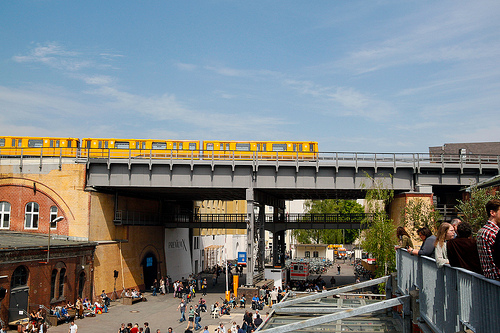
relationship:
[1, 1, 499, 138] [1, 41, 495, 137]
sky has clouds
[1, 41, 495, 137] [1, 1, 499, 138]
clouds in sky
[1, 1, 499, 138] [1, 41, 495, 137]
sky has white clouds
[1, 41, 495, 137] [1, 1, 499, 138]
clouds in blue sky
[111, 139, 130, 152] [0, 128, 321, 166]
window on train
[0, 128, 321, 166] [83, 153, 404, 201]
train on bridge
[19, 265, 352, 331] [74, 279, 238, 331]
people walking on pavement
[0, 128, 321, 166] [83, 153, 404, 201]
train moving on bridge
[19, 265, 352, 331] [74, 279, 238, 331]
people looking street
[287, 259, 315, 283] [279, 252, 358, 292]
ambulance in street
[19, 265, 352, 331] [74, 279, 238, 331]
people standing in street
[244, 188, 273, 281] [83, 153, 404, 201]
metal supporting beams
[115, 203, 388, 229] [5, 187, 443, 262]
walkway between buildings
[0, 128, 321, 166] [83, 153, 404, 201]
train crossing bridge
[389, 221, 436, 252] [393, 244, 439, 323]
people next to fence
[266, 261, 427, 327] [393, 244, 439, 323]
concrete support fence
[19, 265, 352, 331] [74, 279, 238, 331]
people sitting along street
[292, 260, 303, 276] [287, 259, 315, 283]
back of ambulance